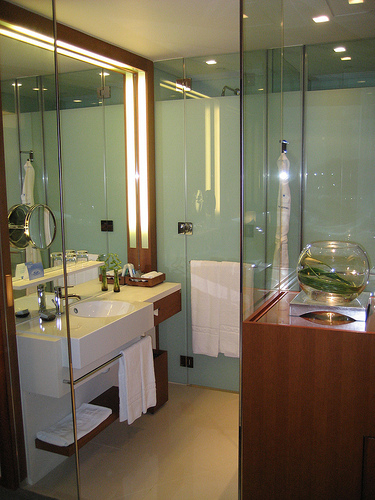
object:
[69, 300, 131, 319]
sink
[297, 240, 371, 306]
fishbowl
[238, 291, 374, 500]
stand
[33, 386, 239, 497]
floor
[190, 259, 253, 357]
towel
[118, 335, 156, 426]
towel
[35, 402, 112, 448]
towel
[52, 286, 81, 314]
faucet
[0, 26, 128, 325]
mirror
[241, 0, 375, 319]
shower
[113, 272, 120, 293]
vase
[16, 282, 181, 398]
counter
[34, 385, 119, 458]
shelf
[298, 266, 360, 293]
foliage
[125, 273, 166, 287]
tray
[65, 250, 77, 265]
glass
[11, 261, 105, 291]
shelf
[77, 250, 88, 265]
glass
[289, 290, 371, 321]
base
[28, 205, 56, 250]
mirror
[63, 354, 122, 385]
rack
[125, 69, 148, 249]
light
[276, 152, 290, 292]
towel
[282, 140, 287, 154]
hook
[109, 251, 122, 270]
plant